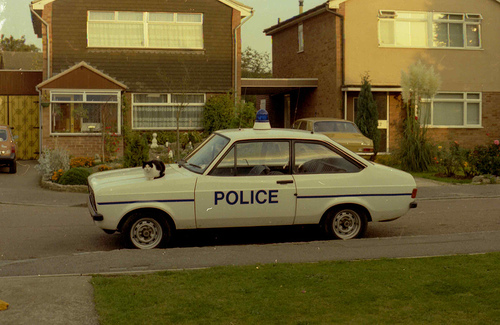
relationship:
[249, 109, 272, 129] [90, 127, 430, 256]
light on roof of car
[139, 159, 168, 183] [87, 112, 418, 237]
cat sitting on police car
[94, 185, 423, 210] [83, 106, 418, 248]
stripe on car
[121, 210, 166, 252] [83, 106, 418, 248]
tire of car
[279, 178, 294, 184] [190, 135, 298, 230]
handle to car door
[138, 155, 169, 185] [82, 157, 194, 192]
cat sitting on hood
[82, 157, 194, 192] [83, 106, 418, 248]
hood of car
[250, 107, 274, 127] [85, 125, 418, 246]
siren on top of car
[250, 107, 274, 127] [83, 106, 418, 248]
siren on top of car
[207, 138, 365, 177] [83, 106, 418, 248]
windows of car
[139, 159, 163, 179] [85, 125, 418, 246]
cat on car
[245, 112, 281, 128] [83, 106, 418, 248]
light on top of car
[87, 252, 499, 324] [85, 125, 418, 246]
grass beside car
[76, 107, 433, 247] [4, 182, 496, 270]
police car parked on street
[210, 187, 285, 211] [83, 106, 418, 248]
black letters on car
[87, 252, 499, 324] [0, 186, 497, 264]
grass beside roadway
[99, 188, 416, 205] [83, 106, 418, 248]
stripe down car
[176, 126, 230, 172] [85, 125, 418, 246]
windshield of car